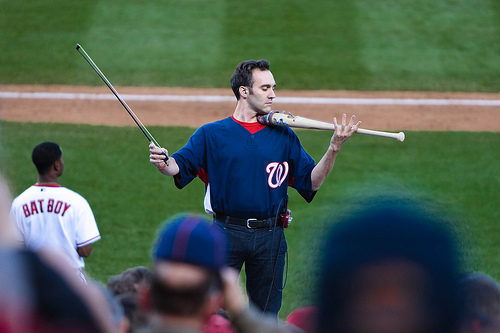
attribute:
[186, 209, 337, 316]
jeans — blue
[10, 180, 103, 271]
jersey — white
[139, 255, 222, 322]
head — bald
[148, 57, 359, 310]
man — man's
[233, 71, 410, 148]
bat — wood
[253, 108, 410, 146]
bat — baseball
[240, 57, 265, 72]
hair — dark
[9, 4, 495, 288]
field — green, grassy, baseball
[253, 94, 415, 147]
baseball bat — wooden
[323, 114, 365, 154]
hand — man's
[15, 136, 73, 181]
head — young man's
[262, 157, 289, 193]
w — white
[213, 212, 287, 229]
belt — black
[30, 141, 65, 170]
hair — short, dark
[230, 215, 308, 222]
belt — leather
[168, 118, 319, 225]
shirt — blue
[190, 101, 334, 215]
shirt — blue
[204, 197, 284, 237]
belt — black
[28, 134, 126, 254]
boy — bat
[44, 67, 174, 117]
line — white